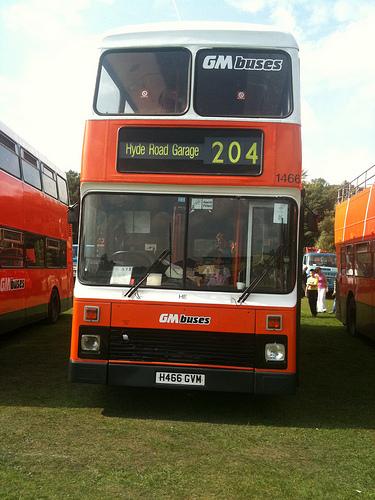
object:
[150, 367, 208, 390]
license plate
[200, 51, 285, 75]
gm buses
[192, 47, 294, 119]
right window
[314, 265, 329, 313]
woman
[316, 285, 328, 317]
skirt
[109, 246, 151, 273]
steering wheel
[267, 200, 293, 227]
paper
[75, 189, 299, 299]
windshield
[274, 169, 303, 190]
1466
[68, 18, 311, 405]
bus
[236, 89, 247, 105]
sticker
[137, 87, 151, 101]
sticker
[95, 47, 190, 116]
left window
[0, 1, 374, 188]
sky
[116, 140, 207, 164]
hyde road garage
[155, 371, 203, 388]
h466 gvm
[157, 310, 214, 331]
gm buses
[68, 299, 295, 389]
bus front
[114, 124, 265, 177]
display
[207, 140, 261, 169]
204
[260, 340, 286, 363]
headlight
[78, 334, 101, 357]
headlight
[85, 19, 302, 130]
second level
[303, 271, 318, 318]
people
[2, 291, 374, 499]
grass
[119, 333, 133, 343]
object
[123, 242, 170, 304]
windshield wiper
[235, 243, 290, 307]
windshield wiper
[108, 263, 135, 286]
sign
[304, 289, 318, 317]
pants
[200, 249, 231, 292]
person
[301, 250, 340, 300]
truck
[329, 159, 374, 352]
bus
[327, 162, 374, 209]
open top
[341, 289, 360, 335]
back tire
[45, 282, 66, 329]
back tire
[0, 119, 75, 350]
bus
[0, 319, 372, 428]
shadow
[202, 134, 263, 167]
number